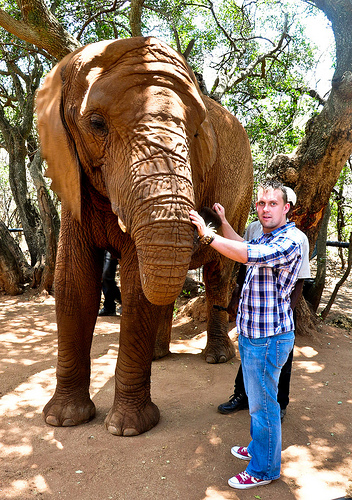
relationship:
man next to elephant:
[191, 176, 315, 481] [30, 28, 265, 438]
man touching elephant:
[191, 176, 315, 481] [30, 28, 265, 438]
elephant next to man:
[30, 28, 265, 438] [191, 176, 315, 481]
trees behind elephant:
[1, 3, 350, 263] [30, 28, 265, 438]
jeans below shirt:
[230, 327, 292, 474] [223, 221, 309, 325]